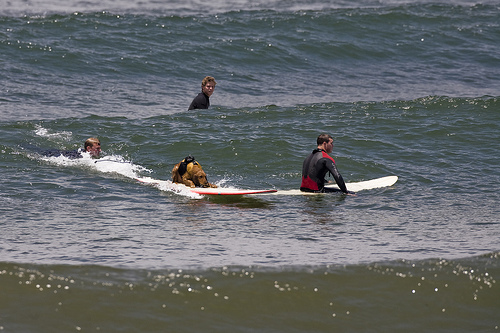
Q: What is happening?
A: Surfing.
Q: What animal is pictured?
A: Dog.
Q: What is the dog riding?
A: A surfboard.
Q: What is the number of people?
A: Three.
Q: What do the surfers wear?
A: Wetsuits.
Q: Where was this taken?
A: The ocean.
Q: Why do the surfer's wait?
A: For waves.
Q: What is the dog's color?
A: Brown.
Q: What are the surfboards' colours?
A: White and orange.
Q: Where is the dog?
A: Surfboard.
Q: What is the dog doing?
A: Surfing.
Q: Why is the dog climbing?
A: Get on board.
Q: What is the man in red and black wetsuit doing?
A: Sitting.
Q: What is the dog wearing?
A: Surf harness.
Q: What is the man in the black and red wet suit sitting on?
A: Surf board.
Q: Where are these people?
A: Ocean.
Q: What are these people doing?
A: Surfing.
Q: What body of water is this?
A: Ocean.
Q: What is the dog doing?
A: Surfing.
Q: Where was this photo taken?
A: The ocean.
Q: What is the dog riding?
A: A surfboard.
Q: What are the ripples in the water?
A: Waves.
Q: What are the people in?
A: Water.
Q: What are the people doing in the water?
A: Surfing.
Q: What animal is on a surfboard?
A: Dog.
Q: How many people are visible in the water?
A: Three.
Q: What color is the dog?
A: Brown.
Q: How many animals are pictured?
A: One.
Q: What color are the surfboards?
A: White.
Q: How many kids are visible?
A: Zero.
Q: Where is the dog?
A: Surfboard.